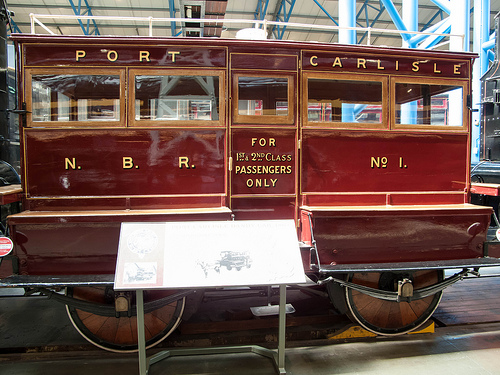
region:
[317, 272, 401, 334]
a wheel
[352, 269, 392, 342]
a wheel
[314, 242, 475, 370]
a wheel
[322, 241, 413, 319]
a wheel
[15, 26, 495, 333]
A little red cart.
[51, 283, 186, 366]
The front tire on the cart.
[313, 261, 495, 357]
The back tire on the cart.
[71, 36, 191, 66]
The text says Port.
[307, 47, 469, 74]
The text says Carlisle.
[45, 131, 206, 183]
The text says N.B.R.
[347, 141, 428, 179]
The text says No. 1.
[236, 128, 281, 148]
The text says For.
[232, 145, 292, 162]
The text says 1st and 2nd class.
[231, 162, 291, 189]
The text says passengers only.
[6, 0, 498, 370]
a museum displaying trains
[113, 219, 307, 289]
an information plate on legs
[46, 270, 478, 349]
the wheels of a train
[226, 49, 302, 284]
a door into the car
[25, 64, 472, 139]
windows are all around the car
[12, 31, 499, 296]
the car is red with wood trim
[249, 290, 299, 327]
a step into the car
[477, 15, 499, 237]
a black train is next to the car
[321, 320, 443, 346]
blocks are keeping the train from rolling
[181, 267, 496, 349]
the floor is wooden under the car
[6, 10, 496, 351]
Train is in a museum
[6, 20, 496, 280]
Train is a bright red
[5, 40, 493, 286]
Train is clean and shiny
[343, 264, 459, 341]
Train has wooden hub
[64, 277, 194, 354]
Wheel has wooden hub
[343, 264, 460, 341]
Wooden hub is brown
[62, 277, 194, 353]
Wooden hub is brown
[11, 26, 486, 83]
Train lettering is gold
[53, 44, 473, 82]
Train lettering say Port Carlisle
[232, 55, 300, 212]
Train door for 1st class passengers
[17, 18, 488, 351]
museum exhibit of an antique trolley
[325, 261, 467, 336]
trolley wheel and metal brace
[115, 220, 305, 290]
sign with information about a trolley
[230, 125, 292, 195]
sign on trolley door describing passengers who are allowed to ride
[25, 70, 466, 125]
windows on a trolley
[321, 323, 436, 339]
yellow wheel stops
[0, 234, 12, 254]
red and white sign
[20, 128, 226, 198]
side of a trolley car reading N. B. R.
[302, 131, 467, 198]
side of a trolley car reading No 1.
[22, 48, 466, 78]
top of trolley car reading PORT CARLISLE